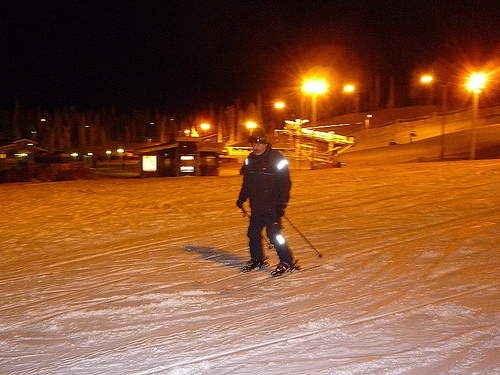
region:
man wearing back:
[236, 123, 291, 277]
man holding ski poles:
[236, 130, 323, 280]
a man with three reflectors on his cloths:
[236, 122, 295, 278]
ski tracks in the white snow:
[3, 156, 498, 371]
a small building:
[131, 136, 226, 176]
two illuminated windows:
[141, 155, 194, 170]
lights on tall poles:
[181, 64, 491, 173]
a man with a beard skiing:
[224, 125, 322, 292]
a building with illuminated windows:
[0, 135, 57, 163]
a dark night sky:
[0, 0, 497, 129]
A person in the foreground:
[209, 119, 339, 287]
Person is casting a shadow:
[170, 228, 248, 279]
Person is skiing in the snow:
[228, 129, 334, 281]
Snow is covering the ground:
[0, 112, 498, 367]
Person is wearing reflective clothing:
[238, 148, 303, 251]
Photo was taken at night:
[1, 4, 494, 374]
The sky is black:
[1, 5, 499, 118]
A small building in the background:
[133, 130, 230, 185]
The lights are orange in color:
[187, 48, 497, 177]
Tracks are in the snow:
[1, 180, 491, 373]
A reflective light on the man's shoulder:
[274, 157, 291, 175]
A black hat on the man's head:
[249, 125, 271, 144]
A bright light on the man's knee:
[275, 234, 289, 245]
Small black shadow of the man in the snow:
[185, 242, 262, 269]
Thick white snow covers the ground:
[7, 172, 486, 372]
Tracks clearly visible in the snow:
[61, 272, 325, 344]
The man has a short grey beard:
[251, 146, 267, 158]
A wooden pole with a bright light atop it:
[456, 64, 493, 164]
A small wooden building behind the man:
[138, 137, 221, 179]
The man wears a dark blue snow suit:
[236, 149, 296, 269]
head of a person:
[240, 126, 280, 154]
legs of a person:
[245, 210, 313, 284]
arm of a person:
[223, 163, 255, 213]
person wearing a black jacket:
[222, 115, 334, 298]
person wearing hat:
[251, 128, 274, 163]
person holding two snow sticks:
[187, 103, 369, 305]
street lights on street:
[271, 52, 337, 132]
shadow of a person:
[179, 223, 236, 270]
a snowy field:
[0, 290, 236, 358]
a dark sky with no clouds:
[65, 43, 216, 102]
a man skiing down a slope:
[228, 125, 322, 277]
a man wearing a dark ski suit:
[236, 130, 299, 277]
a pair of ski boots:
[233, 251, 305, 279]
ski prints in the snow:
[4, 280, 496, 369]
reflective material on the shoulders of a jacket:
[237, 153, 291, 173]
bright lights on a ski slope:
[292, 63, 491, 105]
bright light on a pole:
[460, 61, 493, 162]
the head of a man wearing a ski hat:
[245, 123, 271, 157]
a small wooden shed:
[131, 133, 223, 178]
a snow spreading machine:
[271, 115, 356, 172]